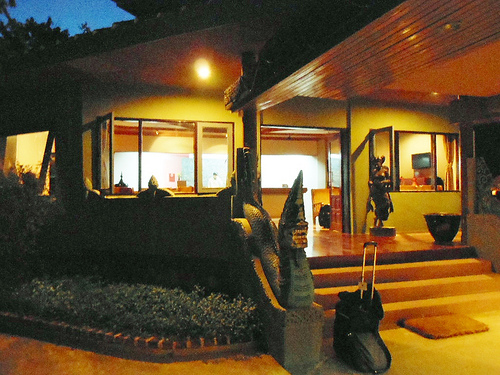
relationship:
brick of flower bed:
[203, 333, 214, 346] [2, 270, 262, 335]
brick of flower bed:
[72, 325, 170, 356] [4, 270, 254, 354]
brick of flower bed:
[178, 340, 192, 352] [54, 271, 240, 363]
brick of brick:
[148, 337, 167, 351] [160, 338, 176, 348]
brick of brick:
[148, 337, 167, 351] [186, 334, 201, 346]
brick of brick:
[148, 337, 167, 351] [199, 334, 217, 348]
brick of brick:
[148, 337, 167, 351] [215, 335, 230, 346]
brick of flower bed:
[148, 337, 167, 351] [3, 309, 261, 359]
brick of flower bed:
[194, 339, 204, 349] [8, 271, 257, 342]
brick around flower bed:
[148, 337, 167, 351] [139, 325, 267, 355]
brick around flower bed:
[148, 337, 167, 351] [3, 264, 262, 344]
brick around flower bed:
[190, 337, 203, 348] [2, 279, 266, 337]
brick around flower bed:
[174, 337, 189, 347] [2, 279, 266, 337]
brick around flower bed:
[162, 337, 174, 350] [2, 279, 266, 337]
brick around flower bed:
[148, 337, 167, 351] [2, 279, 266, 337]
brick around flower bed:
[114, 329, 126, 344] [2, 279, 266, 337]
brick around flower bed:
[0, 309, 257, 355] [2, 270, 262, 335]